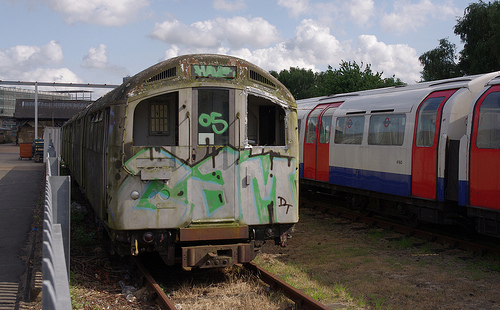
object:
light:
[130, 191, 141, 201]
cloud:
[20, 36, 62, 66]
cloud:
[158, 15, 276, 48]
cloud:
[356, 30, 428, 82]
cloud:
[82, 37, 110, 72]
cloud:
[290, 14, 345, 63]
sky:
[4, 2, 479, 77]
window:
[147, 97, 172, 136]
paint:
[120, 147, 300, 228]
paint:
[412, 92, 441, 195]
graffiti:
[203, 186, 225, 213]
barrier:
[39, 193, 72, 295]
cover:
[16, 97, 92, 119]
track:
[109, 251, 344, 308]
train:
[276, 69, 499, 244]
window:
[366, 112, 406, 147]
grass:
[185, 278, 249, 303]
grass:
[295, 235, 365, 293]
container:
[18, 140, 34, 160]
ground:
[1, 148, 48, 288]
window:
[334, 114, 364, 144]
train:
[54, 52, 302, 276]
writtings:
[250, 177, 278, 227]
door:
[410, 88, 440, 199]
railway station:
[35, 24, 482, 292]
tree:
[270, 59, 402, 98]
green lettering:
[198, 112, 232, 135]